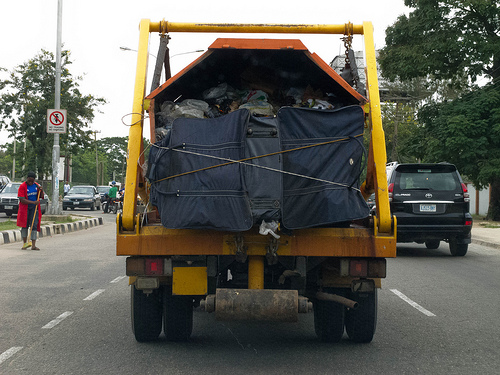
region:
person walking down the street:
[12, 167, 54, 254]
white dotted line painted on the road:
[5, 266, 125, 359]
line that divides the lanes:
[391, 283, 438, 325]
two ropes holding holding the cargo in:
[144, 133, 370, 197]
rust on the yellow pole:
[194, 18, 319, 32]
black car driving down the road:
[366, 150, 477, 260]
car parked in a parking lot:
[56, 176, 100, 213]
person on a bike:
[93, 177, 122, 214]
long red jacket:
[11, 181, 56, 242]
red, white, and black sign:
[38, 103, 73, 133]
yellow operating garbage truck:
[113, 16, 393, 362]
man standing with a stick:
[15, 165, 45, 251]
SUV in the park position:
[380, 155, 480, 266]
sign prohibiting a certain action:
[46, 105, 66, 135]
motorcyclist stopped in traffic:
[100, 180, 120, 215]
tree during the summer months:
[372, 0, 492, 170]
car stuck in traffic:
[57, 181, 99, 207]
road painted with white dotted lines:
[0, 251, 117, 371]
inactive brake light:
[145, 255, 160, 272]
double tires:
[130, 295, 195, 345]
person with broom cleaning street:
[7, 170, 65, 257]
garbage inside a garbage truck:
[160, 46, 365, 162]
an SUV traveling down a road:
[382, 156, 480, 260]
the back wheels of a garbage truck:
[128, 258, 387, 352]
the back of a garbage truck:
[121, 11, 398, 307]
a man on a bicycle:
[100, 176, 128, 219]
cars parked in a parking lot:
[7, 168, 124, 215]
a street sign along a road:
[44, 104, 71, 136]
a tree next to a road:
[391, 27, 499, 164]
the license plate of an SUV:
[417, 202, 438, 213]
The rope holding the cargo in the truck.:
[129, 102, 379, 227]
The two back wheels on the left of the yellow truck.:
[125, 275, 210, 336]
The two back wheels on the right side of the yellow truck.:
[311, 290, 381, 341]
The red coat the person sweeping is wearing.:
[14, 178, 45, 233]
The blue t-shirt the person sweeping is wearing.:
[23, 183, 39, 206]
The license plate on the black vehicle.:
[416, 205, 437, 212]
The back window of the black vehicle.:
[402, 167, 460, 190]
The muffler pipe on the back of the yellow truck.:
[318, 287, 358, 308]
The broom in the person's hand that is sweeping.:
[22, 187, 49, 258]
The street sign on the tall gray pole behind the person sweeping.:
[47, 110, 65, 140]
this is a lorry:
[141, 20, 362, 103]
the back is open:
[198, 48, 311, 113]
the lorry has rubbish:
[227, 55, 294, 110]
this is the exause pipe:
[320, 290, 362, 308]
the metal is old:
[215, 290, 300, 320]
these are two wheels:
[325, 305, 363, 340]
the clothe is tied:
[170, 126, 339, 217]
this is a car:
[400, 157, 466, 254]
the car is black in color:
[423, 191, 458, 223]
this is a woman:
[0, 170, 42, 247]